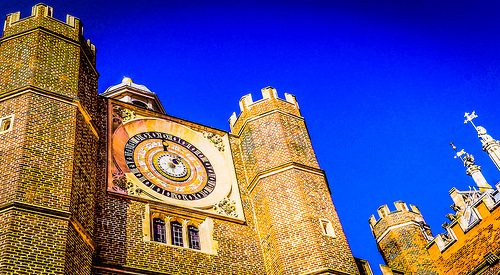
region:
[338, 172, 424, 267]
tower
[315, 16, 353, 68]
white clouds in blue sky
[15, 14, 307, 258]
brown building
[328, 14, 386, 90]
white clouds in blue sky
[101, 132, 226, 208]
clock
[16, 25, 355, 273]
brown castle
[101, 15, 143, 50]
white clouds in blue sky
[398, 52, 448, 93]
white clouds in blue sky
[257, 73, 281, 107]
Red and white flags on top of building.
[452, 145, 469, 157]
Red and white flags on top of building.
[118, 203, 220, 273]
windows on the building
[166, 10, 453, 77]
dark blue sky above land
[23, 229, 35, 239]
A brick in a building.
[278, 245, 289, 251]
A brick in a building.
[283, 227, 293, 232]
A brick in a building.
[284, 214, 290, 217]
A brick in a building.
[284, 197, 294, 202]
A brick in a building.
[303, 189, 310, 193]
A brick in a building.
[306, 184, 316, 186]
A brick in a building.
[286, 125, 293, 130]
A brick in a building.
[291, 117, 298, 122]
A brick in a building.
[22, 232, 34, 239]
A brick in a wall.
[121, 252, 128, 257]
A brick in a wall.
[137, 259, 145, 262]
A brick in a wall.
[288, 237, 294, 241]
A brick in a wall.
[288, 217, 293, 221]
A brick in a wall.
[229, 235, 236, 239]
A brick in a wall.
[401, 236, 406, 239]
A brick in a wall.